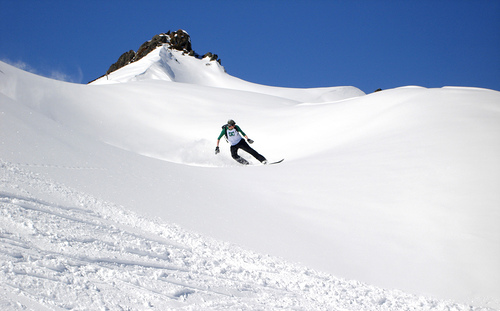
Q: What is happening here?
A: Man is snowboarding.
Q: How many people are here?
A: One.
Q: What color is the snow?
A: White.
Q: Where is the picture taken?
A: On a hill.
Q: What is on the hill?
A: Snow.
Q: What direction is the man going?
A: Right.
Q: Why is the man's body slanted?
A: For balance.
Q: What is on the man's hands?
A: Gloves.